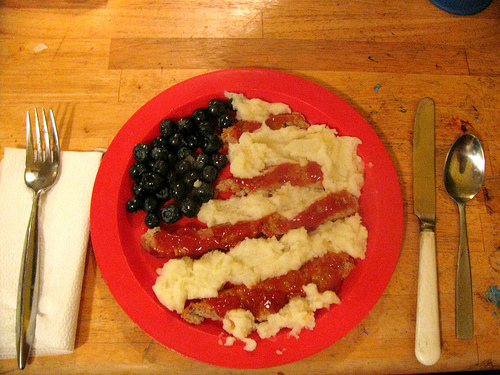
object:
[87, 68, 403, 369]
plate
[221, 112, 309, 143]
ketchup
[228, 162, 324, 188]
ketchup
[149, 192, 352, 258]
ketchup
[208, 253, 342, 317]
ketchup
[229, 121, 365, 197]
mashed potatoes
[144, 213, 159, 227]
blueberries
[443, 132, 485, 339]
spoon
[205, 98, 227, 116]
blueberries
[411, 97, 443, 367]
knife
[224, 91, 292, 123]
food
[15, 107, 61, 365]
fork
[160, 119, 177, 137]
berrie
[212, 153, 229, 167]
berrie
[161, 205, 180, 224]
berrie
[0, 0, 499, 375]
surface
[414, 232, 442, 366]
handle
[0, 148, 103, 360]
napkin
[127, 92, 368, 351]
american flag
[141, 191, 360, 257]
meat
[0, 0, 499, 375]
table